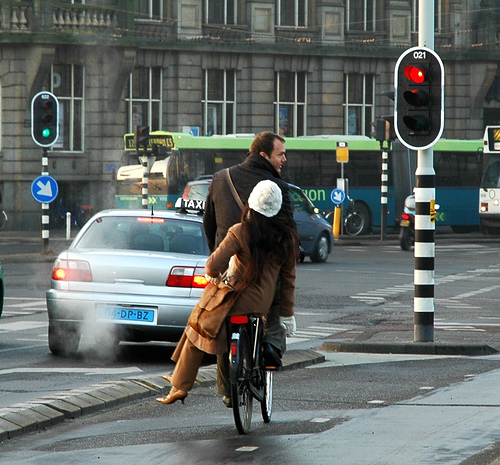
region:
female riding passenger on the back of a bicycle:
[140, 175, 294, 424]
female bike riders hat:
[244, 177, 284, 219]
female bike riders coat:
[178, 211, 302, 359]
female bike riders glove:
[266, 307, 299, 338]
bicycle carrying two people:
[218, 302, 288, 432]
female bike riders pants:
[154, 327, 203, 391]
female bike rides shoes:
[144, 384, 192, 411]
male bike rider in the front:
[190, 131, 298, 282]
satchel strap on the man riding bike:
[217, 162, 247, 210]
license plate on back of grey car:
[94, 298, 158, 325]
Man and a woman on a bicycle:
[158, 128, 298, 440]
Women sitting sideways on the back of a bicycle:
[156, 177, 298, 437]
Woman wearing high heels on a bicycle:
[152, 177, 297, 435]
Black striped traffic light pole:
[391, 0, 450, 345]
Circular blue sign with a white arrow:
[27, 173, 59, 205]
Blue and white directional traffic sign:
[328, 186, 345, 207]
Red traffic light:
[389, 45, 448, 151]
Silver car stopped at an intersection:
[42, 205, 212, 360]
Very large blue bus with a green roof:
[110, 128, 491, 238]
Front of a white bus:
[478, 124, 498, 237]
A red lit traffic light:
[402, 63, 429, 88]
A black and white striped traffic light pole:
[411, 168, 435, 328]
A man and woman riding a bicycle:
[155, 130, 299, 433]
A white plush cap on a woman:
[246, 179, 282, 218]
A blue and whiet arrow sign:
[30, 174, 60, 204]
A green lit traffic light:
[39, 127, 51, 138]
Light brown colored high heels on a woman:
[155, 373, 187, 408]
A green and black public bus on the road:
[111, 129, 498, 245]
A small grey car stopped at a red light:
[43, 206, 213, 353]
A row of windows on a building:
[41, 58, 379, 157]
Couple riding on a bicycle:
[153, 132, 302, 407]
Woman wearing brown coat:
[182, 181, 297, 351]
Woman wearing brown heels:
[153, 378, 189, 406]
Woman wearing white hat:
[246, 177, 285, 218]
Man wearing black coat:
[205, 128, 310, 245]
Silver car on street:
[49, 204, 241, 346]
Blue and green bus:
[121, 137, 490, 231]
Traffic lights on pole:
[394, 45, 445, 339]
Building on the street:
[14, 0, 496, 188]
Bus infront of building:
[117, 134, 487, 234]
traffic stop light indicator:
[376, 40, 478, 369]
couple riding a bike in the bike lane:
[183, 113, 340, 450]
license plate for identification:
[88, 291, 170, 338]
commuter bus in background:
[76, 81, 399, 244]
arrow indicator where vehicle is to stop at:
[16, 169, 66, 228]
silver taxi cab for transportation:
[36, 196, 228, 369]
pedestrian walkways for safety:
[371, 230, 494, 343]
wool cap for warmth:
[246, 179, 294, 238]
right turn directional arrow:
[0, 347, 155, 422]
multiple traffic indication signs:
[324, 124, 410, 260]